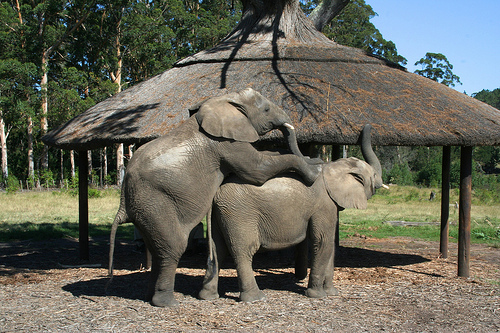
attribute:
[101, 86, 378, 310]
elephants — Grey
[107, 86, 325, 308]
elephant — large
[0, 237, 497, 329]
woodchips — gray, wood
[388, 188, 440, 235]
green grass — tan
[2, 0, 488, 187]
area — Wooded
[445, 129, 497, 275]
post — Man made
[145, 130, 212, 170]
patch — grey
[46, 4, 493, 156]
roof — domed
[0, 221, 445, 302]
shadow — large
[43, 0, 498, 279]
hut — Man made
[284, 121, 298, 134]
tusk — white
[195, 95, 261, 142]
ear — long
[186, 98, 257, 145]
ears — Grey, floppy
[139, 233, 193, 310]
legs — rear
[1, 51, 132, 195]
trunks — white